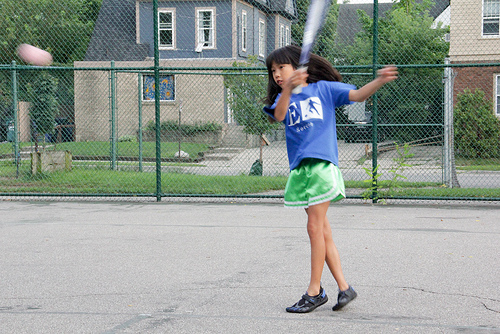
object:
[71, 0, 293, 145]
house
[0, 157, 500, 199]
grass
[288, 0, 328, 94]
bat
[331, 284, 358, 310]
black shoes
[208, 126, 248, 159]
steps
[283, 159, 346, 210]
shorts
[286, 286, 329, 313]
shoe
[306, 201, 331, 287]
legs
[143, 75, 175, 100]
curtain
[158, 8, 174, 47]
window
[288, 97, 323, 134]
emblem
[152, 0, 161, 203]
poles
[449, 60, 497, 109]
brick bottom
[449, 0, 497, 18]
tan top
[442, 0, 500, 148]
house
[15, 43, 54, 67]
ball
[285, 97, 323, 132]
logo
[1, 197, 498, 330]
concrete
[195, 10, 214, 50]
window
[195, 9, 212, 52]
curtain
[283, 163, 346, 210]
stripe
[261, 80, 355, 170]
shirt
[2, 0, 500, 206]
fence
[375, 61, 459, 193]
section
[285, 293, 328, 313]
foot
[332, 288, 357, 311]
foot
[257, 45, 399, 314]
girl